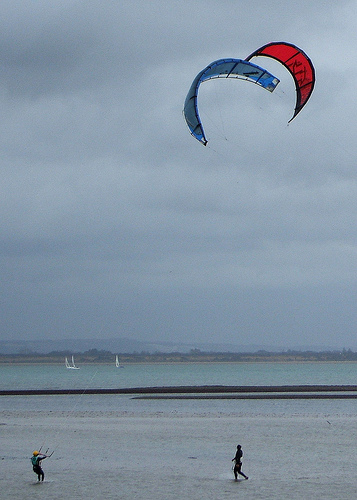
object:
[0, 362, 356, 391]
water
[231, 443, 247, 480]
man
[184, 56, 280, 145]
kite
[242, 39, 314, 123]
kite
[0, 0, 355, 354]
sky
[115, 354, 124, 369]
boat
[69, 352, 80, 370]
boat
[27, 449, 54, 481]
man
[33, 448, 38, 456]
helmet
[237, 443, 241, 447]
hair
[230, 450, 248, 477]
dark clothing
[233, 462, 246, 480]
dark pants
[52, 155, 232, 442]
wires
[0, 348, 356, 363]
moutains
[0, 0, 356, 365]
horizon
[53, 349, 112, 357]
vegetation